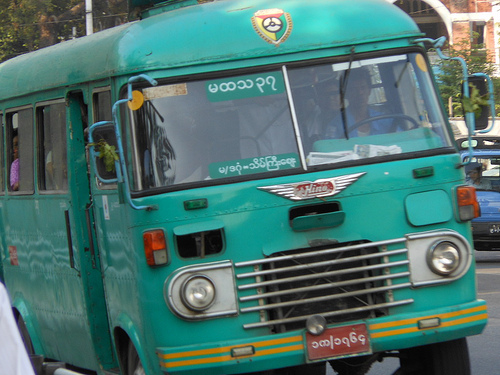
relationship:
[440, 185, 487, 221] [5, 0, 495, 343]
light on bus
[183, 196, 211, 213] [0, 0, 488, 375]
light on automobile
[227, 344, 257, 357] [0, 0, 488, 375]
light on automobile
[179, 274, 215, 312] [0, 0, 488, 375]
headlight on automobile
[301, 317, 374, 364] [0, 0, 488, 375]
license plate on automobile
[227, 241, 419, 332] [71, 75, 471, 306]
grill on van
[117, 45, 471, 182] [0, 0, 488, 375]
windshield on a automobile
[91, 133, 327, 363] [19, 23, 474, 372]
section of a bus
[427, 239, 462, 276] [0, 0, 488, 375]
headlight on automobile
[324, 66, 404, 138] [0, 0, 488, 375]
driver driving automobile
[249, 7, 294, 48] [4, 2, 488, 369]
logo on front of automobile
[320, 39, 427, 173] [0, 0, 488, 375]
driver of automobile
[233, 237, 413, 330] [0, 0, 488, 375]
grill on automobile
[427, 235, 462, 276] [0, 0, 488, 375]
headlight on automobile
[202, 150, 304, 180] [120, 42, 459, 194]
sticker on windshield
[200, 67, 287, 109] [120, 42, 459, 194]
sticker on windshield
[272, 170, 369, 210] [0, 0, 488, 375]
emblem for automobile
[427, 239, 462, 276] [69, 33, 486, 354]
headlight on bus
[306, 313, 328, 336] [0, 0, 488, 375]
light on automobile